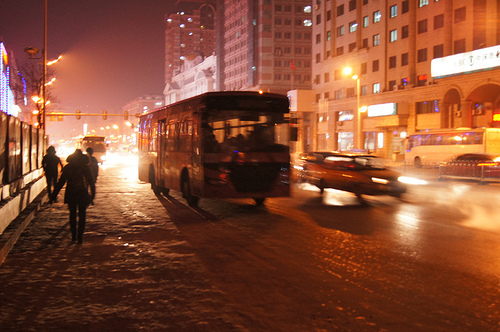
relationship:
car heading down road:
[301, 148, 408, 206] [0, 152, 499, 327]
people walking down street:
[41, 144, 100, 243] [0, 152, 499, 327]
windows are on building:
[314, 4, 467, 95] [307, 2, 499, 160]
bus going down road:
[396, 128, 499, 171] [0, 152, 499, 327]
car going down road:
[301, 148, 408, 206] [0, 152, 499, 327]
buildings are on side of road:
[159, 1, 500, 159] [0, 152, 499, 327]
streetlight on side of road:
[340, 65, 367, 152] [0, 152, 499, 327]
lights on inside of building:
[328, 0, 439, 47] [307, 2, 499, 160]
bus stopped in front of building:
[396, 128, 499, 171] [307, 2, 499, 160]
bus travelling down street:
[138, 87, 300, 206] [0, 152, 499, 327]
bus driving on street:
[138, 87, 300, 206] [0, 152, 499, 327]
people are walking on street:
[41, 144, 100, 243] [0, 152, 499, 327]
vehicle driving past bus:
[301, 148, 408, 206] [138, 87, 300, 206]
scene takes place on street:
[0, 1, 499, 332] [0, 152, 499, 327]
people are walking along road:
[41, 144, 100, 243] [0, 152, 499, 327]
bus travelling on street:
[138, 87, 300, 206] [0, 152, 499, 327]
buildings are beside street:
[159, 1, 500, 159] [0, 152, 499, 327]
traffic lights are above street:
[74, 110, 130, 121] [0, 152, 499, 327]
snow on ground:
[3, 167, 239, 331] [0, 152, 499, 327]